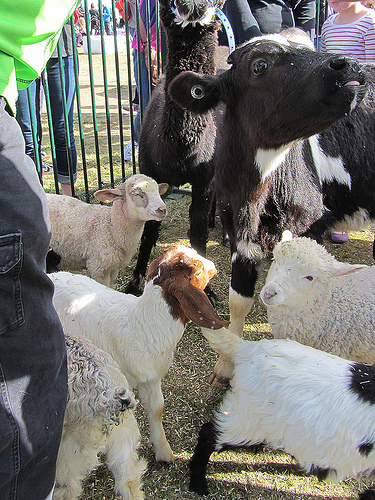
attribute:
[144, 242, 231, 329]
head — Brown and white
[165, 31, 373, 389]
cow — black and white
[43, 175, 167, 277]
lamb — cream, gray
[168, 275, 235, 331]
ear — Long , brown 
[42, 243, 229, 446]
goat. — brown and white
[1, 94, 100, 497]
jeans — blue jeans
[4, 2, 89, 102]
shirt — bright green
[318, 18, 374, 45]
stripes — red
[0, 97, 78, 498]
jeans — black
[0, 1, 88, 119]
shirt — green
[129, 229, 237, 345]
animal — brown and white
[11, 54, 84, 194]
jeans — cropped, cuffed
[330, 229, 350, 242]
shoe — purple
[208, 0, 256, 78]
tag — animal's neck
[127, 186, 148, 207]
patch — dark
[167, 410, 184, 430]
leaves —  small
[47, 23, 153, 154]
gate — iron, green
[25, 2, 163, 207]
gate — metal, green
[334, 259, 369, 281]
sheep's ear — furry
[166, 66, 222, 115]
sheep's ear — black, furry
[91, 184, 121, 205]
sheep's ear — furry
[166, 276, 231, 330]
sheep's ear — furry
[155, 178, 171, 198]
sheep's ear — furry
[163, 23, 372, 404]
calf — white, black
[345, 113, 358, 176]
tag — round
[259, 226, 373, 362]
lamb — white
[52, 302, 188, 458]
fur — white and black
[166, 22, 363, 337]
goat — white, black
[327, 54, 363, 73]
nose — black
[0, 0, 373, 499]
zoo — petting zoo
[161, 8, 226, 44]
neck — animals neck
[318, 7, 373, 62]
shirt — white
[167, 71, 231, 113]
ear — cows ear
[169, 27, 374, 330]
cow — black and white, baby cow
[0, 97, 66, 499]
pants — black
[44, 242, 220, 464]
goat — white, brown